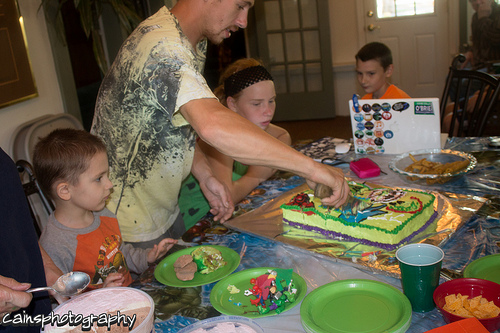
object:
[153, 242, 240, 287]
plate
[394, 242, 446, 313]
cup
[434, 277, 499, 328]
bowl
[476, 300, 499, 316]
chips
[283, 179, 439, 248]
cake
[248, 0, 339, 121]
door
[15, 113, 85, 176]
chair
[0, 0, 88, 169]
wall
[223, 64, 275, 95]
headband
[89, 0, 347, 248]
man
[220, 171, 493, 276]
tinfoil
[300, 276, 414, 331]
plates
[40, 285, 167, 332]
tub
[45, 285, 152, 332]
ice cream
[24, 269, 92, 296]
spoon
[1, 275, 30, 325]
hand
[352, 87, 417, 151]
shirt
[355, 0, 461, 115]
door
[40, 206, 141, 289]
shirt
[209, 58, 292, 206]
girl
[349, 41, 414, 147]
boy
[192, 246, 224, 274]
cake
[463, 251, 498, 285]
plate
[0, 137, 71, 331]
person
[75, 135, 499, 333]
table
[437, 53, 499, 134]
chair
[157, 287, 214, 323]
hulk